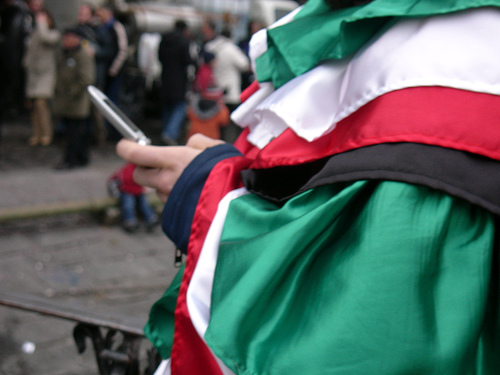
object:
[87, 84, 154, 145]
phone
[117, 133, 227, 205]
hand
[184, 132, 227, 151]
thumb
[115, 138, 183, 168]
index finger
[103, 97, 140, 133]
screen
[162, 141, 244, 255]
sleeve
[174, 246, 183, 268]
zipper pull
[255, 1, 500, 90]
fabric ruffle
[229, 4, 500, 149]
fabric ruffle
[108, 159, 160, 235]
person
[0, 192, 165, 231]
curb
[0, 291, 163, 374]
railing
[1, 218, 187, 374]
road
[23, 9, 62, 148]
lady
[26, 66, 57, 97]
skirt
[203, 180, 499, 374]
sleeve layer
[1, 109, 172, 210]
sidewalk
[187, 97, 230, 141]
jacket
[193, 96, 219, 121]
hood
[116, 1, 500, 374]
person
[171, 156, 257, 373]
sleeve layer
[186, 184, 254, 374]
sleeve layer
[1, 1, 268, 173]
crowd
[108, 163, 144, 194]
shirt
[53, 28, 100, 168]
person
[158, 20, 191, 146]
person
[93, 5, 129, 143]
person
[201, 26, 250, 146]
person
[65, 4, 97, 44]
person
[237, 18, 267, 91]
person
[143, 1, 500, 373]
clothing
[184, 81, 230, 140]
person